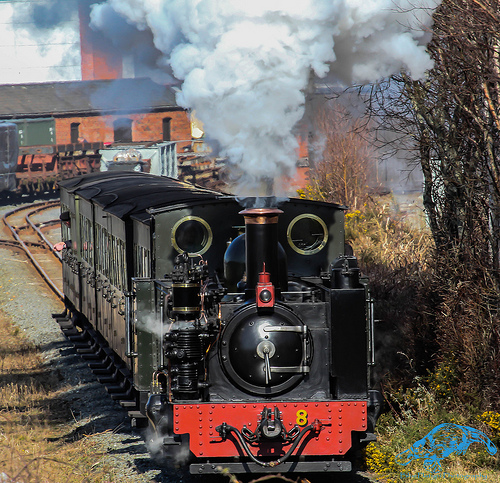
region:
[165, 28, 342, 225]
Smoke coming out of the stack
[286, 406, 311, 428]
Number on the front of the train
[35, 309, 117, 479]
Shadow on the ground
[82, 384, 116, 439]
Gravel beside the track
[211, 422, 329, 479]
Pipe on front of the train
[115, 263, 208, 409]
Small smoke stack on the front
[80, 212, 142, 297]
Windows on side of train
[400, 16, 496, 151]
Tree has lost all its leaves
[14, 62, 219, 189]
Building beside the track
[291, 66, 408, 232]
Small bush on side of track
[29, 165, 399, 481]
this is a train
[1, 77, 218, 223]
this is a house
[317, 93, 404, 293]
this is a bushy tree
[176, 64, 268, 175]
a cloud of smoke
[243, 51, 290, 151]
a cloud of smoke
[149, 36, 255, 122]
a cloud of smoke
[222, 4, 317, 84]
a cloud of smoke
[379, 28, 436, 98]
a cloud of smoke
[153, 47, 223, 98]
a cloud of smoke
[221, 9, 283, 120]
a cloud of smoke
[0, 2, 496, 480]
A train is traveling down the tracks.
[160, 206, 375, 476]
The front of the train is black and red.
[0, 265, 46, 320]
The gravel near the tracks is called track ballast.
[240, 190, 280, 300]
A smoke stack on the train.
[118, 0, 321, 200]
Smoke is coming out of the stack.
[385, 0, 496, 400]
A tree is next to the train.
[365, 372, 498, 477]
Small plants are growing near the tree.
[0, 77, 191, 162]
A red brick building in distance.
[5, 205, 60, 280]
Two steel rails on the train tracks.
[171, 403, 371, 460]
Part of the train is red.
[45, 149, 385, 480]
a locomotive on the railroad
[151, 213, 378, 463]
front of locomotive is black and red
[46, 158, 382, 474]
locomotive is color black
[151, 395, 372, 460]
bumper of locomotive is red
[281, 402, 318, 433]
a yellow number 8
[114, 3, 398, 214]
smoke coming out the locomotive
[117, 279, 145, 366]
a handle on side the train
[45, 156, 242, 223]
roof of train is black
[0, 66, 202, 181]
a red building of brick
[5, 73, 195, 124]
roof of building is black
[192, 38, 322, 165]
large area of white smoke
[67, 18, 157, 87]
black soot in white smoke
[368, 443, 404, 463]
tiny yellow leaves on the ground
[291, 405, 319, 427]
large yellow number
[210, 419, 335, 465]
thick black iron on front of train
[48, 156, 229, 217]
black top on train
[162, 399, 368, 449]
red front on the train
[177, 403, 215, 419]
tiny bolts on front of train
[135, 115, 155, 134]
red and black bricks on wall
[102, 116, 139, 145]
tall black door in building